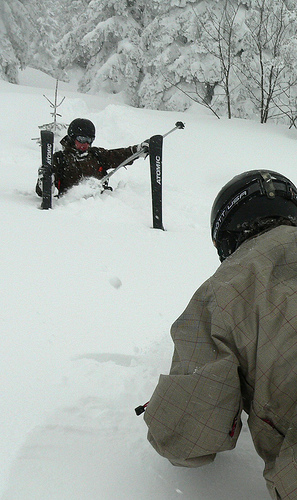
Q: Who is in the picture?
A: A man and woman.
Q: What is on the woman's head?
A: A helmet.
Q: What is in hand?
A: A ski pole.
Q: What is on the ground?
A: Snow.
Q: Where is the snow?
A: On the ground.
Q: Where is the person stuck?
A: In the snow.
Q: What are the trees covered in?
A: Snow.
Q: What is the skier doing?
A: Sitting.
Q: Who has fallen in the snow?
A: The skier.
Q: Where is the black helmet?
A: On the head of the skier.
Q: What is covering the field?
A: Snow.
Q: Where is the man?
A: In the snow.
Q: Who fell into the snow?
A: A skier.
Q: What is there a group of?
A: Leafless trees.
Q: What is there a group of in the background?
A: Pine trees.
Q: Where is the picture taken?
A: Outdoors`.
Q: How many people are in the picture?
A: Two.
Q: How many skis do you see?
A: Two.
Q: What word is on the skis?
A: Atomic.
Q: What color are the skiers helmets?
A: Black.